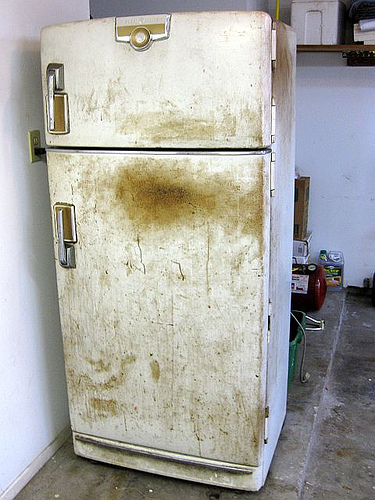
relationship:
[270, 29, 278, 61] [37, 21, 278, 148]
hinge on door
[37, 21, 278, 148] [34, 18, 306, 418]
door on refrigeratior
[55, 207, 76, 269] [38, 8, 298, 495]
handle on fridge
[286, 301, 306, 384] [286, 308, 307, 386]
basket contains basket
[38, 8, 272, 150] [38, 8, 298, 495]
door of fridge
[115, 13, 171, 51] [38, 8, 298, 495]
logo on fridge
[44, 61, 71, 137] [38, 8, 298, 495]
handle on fridge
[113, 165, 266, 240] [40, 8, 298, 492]
dirt spot on fridge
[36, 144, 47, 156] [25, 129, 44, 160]
power cord in outlet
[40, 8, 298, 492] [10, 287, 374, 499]
fridge on concrete ground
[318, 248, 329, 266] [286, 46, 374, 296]
bottle against wall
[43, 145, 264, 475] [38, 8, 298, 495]
door on fridge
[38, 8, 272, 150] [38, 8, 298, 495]
door on fridge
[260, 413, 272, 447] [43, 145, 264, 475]
hinge on door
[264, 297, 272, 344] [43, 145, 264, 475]
hinge on door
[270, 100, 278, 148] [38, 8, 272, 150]
hinge on door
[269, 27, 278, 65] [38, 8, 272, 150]
hinge on door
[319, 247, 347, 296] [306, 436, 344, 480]
bottle sitting on floor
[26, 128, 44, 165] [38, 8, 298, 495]
plug behind fridge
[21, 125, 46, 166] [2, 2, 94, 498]
plug on wall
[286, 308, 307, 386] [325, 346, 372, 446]
basket on ground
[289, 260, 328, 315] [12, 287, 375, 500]
pump on floor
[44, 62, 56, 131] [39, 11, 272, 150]
handle on freezer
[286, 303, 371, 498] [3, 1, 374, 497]
floor in room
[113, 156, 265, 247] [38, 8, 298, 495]
dirt spot on fridge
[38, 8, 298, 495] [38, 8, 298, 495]
fridge of fridge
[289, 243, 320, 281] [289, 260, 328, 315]
pump of pump